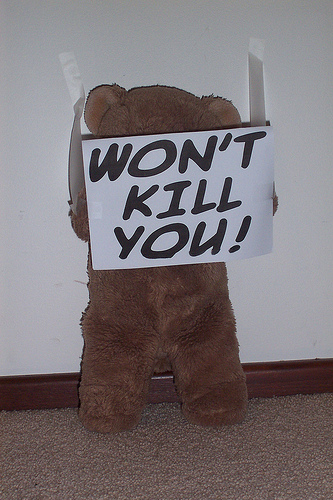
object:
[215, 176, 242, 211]
letter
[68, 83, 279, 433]
stuffed bear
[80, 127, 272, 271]
sign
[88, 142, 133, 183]
letter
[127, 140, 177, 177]
letter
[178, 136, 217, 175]
letter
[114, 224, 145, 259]
letter